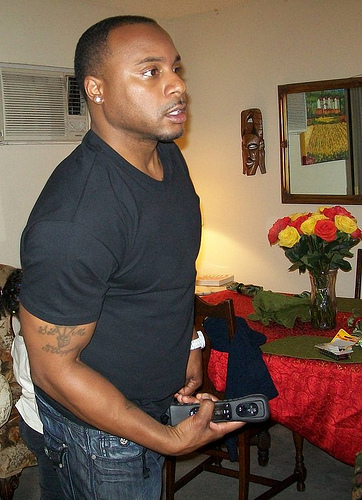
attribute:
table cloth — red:
[203, 285, 332, 429]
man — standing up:
[12, 8, 243, 497]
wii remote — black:
[162, 382, 276, 437]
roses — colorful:
[261, 200, 360, 266]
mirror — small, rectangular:
[275, 74, 360, 208]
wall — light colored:
[189, 10, 273, 257]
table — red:
[203, 282, 360, 451]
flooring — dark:
[178, 443, 360, 499]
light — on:
[202, 223, 252, 286]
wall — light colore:
[177, 5, 356, 280]